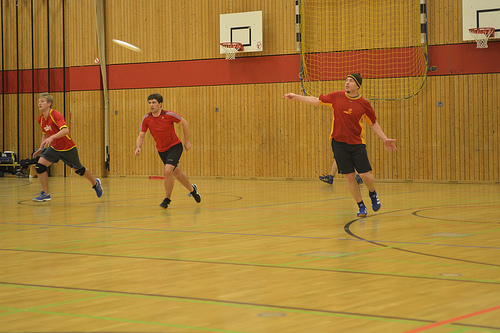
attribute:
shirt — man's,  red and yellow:
[316, 91, 379, 146]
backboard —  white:
[218, 8, 263, 59]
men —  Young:
[16, 84, 397, 242]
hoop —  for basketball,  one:
[190, 19, 307, 69]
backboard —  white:
[203, 0, 284, 40]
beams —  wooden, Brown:
[15, 10, 106, 111]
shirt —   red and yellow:
[316, 90, 409, 166]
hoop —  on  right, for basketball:
[465, 23, 492, 53]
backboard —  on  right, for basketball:
[457, 5, 492, 46]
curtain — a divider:
[91, 1, 108, 174]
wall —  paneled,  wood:
[217, 107, 288, 158]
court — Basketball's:
[24, 167, 483, 317]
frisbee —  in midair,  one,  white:
[110, 28, 140, 62]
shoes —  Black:
[152, 195, 203, 210]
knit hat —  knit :
[344, 69, 365, 86]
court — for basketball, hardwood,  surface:
[2, 175, 499, 332]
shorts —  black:
[332, 140, 376, 178]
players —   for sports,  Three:
[28, 71, 390, 216]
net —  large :
[294, 4, 428, 106]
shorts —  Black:
[152, 147, 185, 165]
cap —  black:
[342, 64, 413, 105]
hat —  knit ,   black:
[344, 72, 370, 88]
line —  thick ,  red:
[3, 36, 498, 93]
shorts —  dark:
[330, 140, 373, 173]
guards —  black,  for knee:
[33, 160, 49, 176]